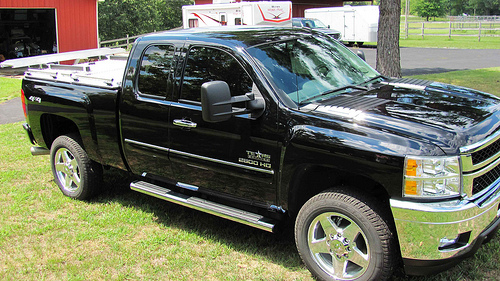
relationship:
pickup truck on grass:
[19, 26, 500, 281] [78, 210, 125, 257]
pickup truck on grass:
[19, 26, 500, 281] [161, 231, 191, 265]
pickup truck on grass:
[19, 26, 500, 281] [114, 205, 172, 269]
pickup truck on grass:
[19, 26, 500, 281] [179, 240, 226, 271]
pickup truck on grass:
[19, 26, 500, 281] [114, 221, 184, 259]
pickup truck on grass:
[19, 26, 500, 281] [133, 219, 188, 259]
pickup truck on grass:
[19, 26, 500, 281] [123, 206, 176, 269]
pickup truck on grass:
[19, 26, 500, 281] [123, 218, 187, 269]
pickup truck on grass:
[19, 26, 500, 281] [84, 211, 160, 262]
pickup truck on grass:
[19, 26, 500, 281] [95, 214, 172, 274]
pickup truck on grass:
[19, 26, 500, 281] [95, 208, 155, 255]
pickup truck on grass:
[19, 26, 500, 281] [68, 211, 154, 261]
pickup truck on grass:
[19, 26, 500, 281] [101, 214, 176, 266]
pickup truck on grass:
[19, 26, 500, 281] [131, 226, 160, 266]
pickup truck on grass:
[19, 26, 500, 281] [96, 207, 129, 251]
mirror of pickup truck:
[198, 83, 233, 122] [19, 26, 500, 281]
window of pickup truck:
[146, 48, 165, 101] [19, 26, 500, 281]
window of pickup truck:
[267, 42, 361, 80] [19, 26, 500, 281]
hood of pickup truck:
[358, 85, 484, 135] [19, 26, 500, 281]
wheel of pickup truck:
[285, 190, 377, 280] [19, 26, 500, 281]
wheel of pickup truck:
[55, 140, 96, 190] [19, 26, 500, 281]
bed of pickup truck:
[24, 48, 131, 91] [19, 26, 500, 281]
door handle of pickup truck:
[173, 120, 198, 128] [19, 26, 500, 281]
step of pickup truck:
[166, 197, 236, 209] [19, 26, 500, 281]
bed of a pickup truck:
[34, 48, 117, 91] [16, 20, 492, 272]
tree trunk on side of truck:
[374, 15, 399, 71] [121, 30, 446, 266]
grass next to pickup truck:
[96, 195, 134, 235] [19, 26, 500, 281]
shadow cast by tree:
[405, 60, 455, 81] [367, 0, 423, 112]